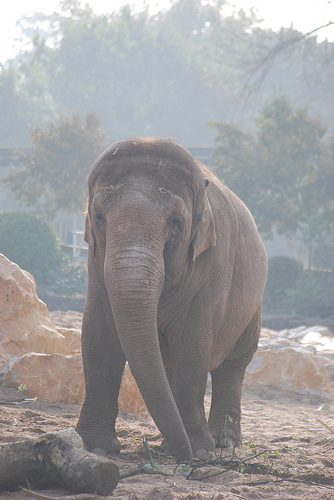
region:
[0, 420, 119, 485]
log is grey and dead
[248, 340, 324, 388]
rock is tan and heavy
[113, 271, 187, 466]
trunk is long useful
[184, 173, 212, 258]
ear is big and gray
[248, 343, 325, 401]
rock is big and heavy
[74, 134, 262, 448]
elephant is large and happy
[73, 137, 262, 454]
elephant is big and lumbering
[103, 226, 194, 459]
The trunk of the elephant.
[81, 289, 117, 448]
The front left leg of the elephant.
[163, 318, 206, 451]
The front right leg of the elephant.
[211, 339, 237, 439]
The back right leg of the elephant.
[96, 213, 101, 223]
The left eye of the elephant.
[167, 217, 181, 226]
The right eye of the elephant.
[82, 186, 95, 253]
The left ear of the elephant.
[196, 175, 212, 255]
The right ear of the elephant.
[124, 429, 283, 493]
The branches near the elephant's feet.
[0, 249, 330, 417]
The rocks behind the elephant.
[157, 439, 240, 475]
the branches are thin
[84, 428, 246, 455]
feet in the dirt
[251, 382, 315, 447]
the dirt is tan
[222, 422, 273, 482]
leaves on the branches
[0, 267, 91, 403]
the rocks are orange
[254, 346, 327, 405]
rocks in the sand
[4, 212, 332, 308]
bushes behind the elephant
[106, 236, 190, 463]
the trunk is long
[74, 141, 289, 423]
the elephant is dark gray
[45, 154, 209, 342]
the skin is wrinkly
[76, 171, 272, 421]
the elephant is very big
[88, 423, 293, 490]
the ground is dirt and mud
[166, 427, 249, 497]
the mud is light brown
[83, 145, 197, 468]
elelphant's trunk is long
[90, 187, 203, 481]
elelphant's trunk is long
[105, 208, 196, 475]
elelphant's trunk is long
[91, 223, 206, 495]
elelphant's trunk is long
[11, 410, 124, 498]
a log on the ground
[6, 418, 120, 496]
a log on the ground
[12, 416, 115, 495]
a log on the ground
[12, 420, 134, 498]
a log on the ground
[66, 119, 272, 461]
this is an elephant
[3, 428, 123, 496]
this is a log of wood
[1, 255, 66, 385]
this is a rock